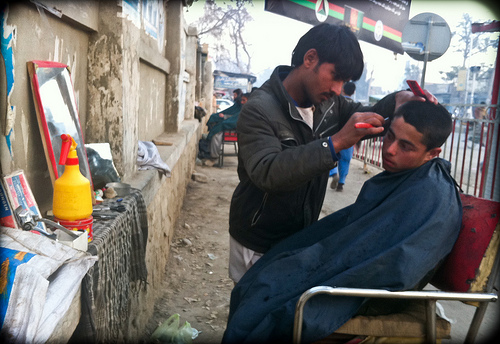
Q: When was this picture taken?
A: During the day.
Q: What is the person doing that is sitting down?
A: Getting his haircut.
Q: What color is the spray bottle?
A: Yellow and red.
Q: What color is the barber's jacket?
A: Black.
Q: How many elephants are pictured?
A: Zero.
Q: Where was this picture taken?
A: At a barber shop.